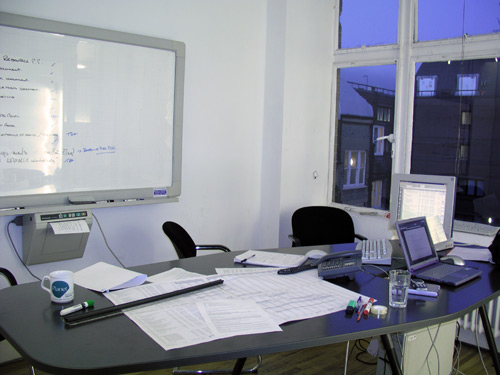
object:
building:
[334, 56, 499, 221]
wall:
[411, 96, 500, 179]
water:
[389, 286, 409, 304]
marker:
[59, 299, 94, 317]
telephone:
[315, 250, 362, 279]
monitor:
[389, 173, 457, 239]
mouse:
[305, 249, 328, 259]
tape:
[370, 305, 388, 315]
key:
[427, 270, 430, 272]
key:
[369, 244, 374, 248]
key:
[370, 241, 373, 243]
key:
[382, 242, 386, 245]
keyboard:
[361, 239, 392, 266]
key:
[377, 250, 380, 253]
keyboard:
[418, 263, 464, 279]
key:
[443, 268, 447, 271]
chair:
[288, 206, 369, 248]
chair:
[161, 221, 231, 260]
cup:
[40, 270, 76, 304]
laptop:
[395, 216, 484, 288]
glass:
[388, 270, 412, 308]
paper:
[195, 298, 284, 337]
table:
[0, 237, 499, 374]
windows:
[329, 0, 499, 229]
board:
[0, 13, 186, 217]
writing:
[0, 56, 41, 99]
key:
[437, 272, 439, 274]